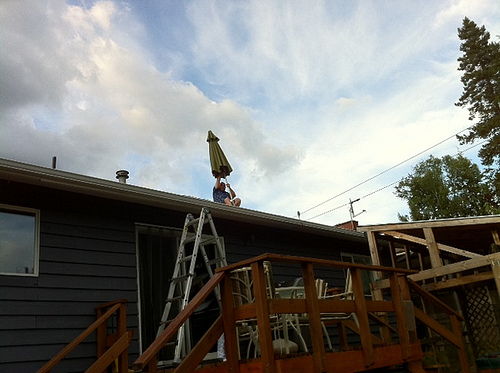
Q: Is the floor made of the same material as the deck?
A: Yes, both the floor and the deck are made of wood.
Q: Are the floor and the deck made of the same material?
A: Yes, both the floor and the deck are made of wood.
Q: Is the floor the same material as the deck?
A: Yes, both the floor and the deck are made of wood.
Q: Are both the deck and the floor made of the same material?
A: Yes, both the deck and the floor are made of wood.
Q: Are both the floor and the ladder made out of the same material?
A: No, the floor is made of wood and the ladder is made of metal.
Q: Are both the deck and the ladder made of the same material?
A: No, the deck is made of wood and the ladder is made of metal.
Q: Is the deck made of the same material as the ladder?
A: No, the deck is made of wood and the ladder is made of metal.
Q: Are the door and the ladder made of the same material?
A: No, the door is made of glass and the ladder is made of metal.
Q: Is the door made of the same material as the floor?
A: No, the door is made of glass and the floor is made of wood.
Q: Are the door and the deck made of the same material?
A: No, the door is made of glass and the deck is made of wood.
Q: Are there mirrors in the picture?
A: No, there are no mirrors.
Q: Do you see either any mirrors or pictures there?
A: No, there are no mirrors or pictures.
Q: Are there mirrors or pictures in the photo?
A: No, there are no mirrors or pictures.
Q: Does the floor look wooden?
A: Yes, the floor is wooden.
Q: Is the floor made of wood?
A: Yes, the floor is made of wood.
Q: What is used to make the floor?
A: The floor is made of wood.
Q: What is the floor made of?
A: The floor is made of wood.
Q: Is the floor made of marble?
A: No, the floor is made of wood.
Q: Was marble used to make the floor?
A: No, the floor is made of wood.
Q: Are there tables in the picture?
A: Yes, there is a table.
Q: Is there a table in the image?
A: Yes, there is a table.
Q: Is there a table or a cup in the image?
A: Yes, there is a table.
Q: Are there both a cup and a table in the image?
A: No, there is a table but no cups.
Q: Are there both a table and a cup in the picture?
A: No, there is a table but no cups.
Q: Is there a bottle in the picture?
A: No, there are no bottles.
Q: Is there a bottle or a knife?
A: No, there are no bottles or knives.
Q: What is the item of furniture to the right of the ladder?
A: The piece of furniture is a table.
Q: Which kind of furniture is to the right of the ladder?
A: The piece of furniture is a table.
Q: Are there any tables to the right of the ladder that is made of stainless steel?
A: Yes, there is a table to the right of the ladder.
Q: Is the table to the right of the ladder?
A: Yes, the table is to the right of the ladder.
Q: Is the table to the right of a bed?
A: No, the table is to the right of the ladder.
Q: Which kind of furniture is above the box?
A: The piece of furniture is a table.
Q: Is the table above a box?
A: Yes, the table is above a box.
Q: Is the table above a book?
A: No, the table is above a box.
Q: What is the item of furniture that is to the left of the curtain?
A: The piece of furniture is a table.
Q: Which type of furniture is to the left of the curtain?
A: The piece of furniture is a table.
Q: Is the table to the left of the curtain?
A: Yes, the table is to the left of the curtain.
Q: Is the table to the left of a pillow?
A: No, the table is to the left of the curtain.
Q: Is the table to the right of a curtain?
A: No, the table is to the left of a curtain.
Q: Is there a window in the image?
A: Yes, there is a window.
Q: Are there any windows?
A: Yes, there is a window.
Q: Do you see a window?
A: Yes, there is a window.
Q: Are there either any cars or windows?
A: Yes, there is a window.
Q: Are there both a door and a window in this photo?
A: Yes, there are both a window and a door.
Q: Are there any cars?
A: No, there are no cars.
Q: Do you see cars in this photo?
A: No, there are no cars.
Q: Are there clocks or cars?
A: No, there are no cars or clocks.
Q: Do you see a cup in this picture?
A: No, there are no cups.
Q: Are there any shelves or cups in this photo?
A: No, there are no cups or shelves.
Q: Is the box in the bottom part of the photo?
A: Yes, the box is in the bottom of the image.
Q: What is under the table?
A: The box is under the table.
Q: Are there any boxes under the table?
A: Yes, there is a box under the table.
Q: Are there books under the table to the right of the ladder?
A: No, there is a box under the table.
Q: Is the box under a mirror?
A: No, the box is under a table.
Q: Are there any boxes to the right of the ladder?
A: Yes, there is a box to the right of the ladder.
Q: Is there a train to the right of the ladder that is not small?
A: No, there is a box to the right of the ladder.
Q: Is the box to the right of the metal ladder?
A: Yes, the box is to the right of the ladder.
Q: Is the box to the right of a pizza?
A: No, the box is to the right of the ladder.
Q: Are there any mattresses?
A: No, there are no mattresses.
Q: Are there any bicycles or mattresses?
A: No, there are no mattresses or bicycles.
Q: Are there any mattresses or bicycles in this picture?
A: No, there are no mattresses or bicycles.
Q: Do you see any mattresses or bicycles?
A: No, there are no mattresses or bicycles.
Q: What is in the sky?
A: The clouds are in the sky.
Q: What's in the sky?
A: The clouds are in the sky.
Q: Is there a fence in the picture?
A: No, there are no fences.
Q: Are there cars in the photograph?
A: No, there are no cars.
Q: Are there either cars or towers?
A: No, there are no cars or towers.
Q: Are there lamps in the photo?
A: No, there are no lamps.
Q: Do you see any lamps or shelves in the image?
A: No, there are no lamps or shelves.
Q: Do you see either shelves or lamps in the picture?
A: No, there are no lamps or shelves.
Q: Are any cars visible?
A: No, there are no cars.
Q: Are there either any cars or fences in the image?
A: No, there are no cars or fences.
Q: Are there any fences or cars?
A: No, there are no cars or fences.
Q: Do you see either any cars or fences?
A: No, there are no cars or fences.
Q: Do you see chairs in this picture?
A: Yes, there is a chair.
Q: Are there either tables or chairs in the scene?
A: Yes, there is a chair.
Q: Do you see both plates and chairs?
A: No, there is a chair but no plates.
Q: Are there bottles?
A: No, there are no bottles.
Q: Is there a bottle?
A: No, there are no bottles.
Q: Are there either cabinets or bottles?
A: No, there are no bottles or cabinets.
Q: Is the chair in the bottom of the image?
A: Yes, the chair is in the bottom of the image.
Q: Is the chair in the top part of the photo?
A: No, the chair is in the bottom of the image.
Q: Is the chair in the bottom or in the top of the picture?
A: The chair is in the bottom of the image.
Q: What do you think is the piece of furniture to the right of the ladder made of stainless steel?
A: The piece of furniture is a chair.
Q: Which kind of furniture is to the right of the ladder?
A: The piece of furniture is a chair.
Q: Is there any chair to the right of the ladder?
A: Yes, there is a chair to the right of the ladder.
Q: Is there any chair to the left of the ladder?
A: No, the chair is to the right of the ladder.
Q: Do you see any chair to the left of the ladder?
A: No, the chair is to the right of the ladder.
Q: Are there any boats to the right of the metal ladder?
A: No, there is a chair to the right of the ladder.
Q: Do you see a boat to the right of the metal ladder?
A: No, there is a chair to the right of the ladder.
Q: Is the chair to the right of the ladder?
A: Yes, the chair is to the right of the ladder.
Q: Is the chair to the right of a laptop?
A: No, the chair is to the right of the ladder.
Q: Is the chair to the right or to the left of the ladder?
A: The chair is to the right of the ladder.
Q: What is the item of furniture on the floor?
A: The piece of furniture is a chair.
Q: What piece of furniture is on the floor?
A: The piece of furniture is a chair.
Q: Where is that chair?
A: The chair is on the floor.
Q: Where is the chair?
A: The chair is on the floor.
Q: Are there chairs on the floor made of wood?
A: Yes, there is a chair on the floor.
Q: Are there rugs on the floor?
A: No, there is a chair on the floor.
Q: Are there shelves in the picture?
A: No, there are no shelves.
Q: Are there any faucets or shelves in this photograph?
A: No, there are no shelves or faucets.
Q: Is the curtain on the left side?
A: No, the curtain is on the right of the image.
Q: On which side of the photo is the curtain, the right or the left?
A: The curtain is on the right of the image.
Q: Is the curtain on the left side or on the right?
A: The curtain is on the right of the image.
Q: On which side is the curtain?
A: The curtain is on the right of the image.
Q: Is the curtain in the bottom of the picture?
A: Yes, the curtain is in the bottom of the image.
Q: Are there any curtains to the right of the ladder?
A: Yes, there is a curtain to the right of the ladder.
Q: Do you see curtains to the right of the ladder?
A: Yes, there is a curtain to the right of the ladder.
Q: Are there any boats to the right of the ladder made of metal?
A: No, there is a curtain to the right of the ladder.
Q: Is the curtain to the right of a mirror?
A: No, the curtain is to the right of a ladder.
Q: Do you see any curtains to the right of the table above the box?
A: Yes, there is a curtain to the right of the table.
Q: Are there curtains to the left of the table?
A: No, the curtain is to the right of the table.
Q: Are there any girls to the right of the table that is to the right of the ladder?
A: No, there is a curtain to the right of the table.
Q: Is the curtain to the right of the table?
A: Yes, the curtain is to the right of the table.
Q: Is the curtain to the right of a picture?
A: No, the curtain is to the right of the table.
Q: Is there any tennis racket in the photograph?
A: No, there are no rackets.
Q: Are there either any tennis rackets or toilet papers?
A: No, there are no tennis rackets or toilet papers.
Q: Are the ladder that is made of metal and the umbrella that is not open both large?
A: Yes, both the ladder and the umbrella are large.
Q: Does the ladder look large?
A: Yes, the ladder is large.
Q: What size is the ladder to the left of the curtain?
A: The ladder is large.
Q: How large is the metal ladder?
A: The ladder is large.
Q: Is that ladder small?
A: No, the ladder is large.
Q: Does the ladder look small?
A: No, the ladder is large.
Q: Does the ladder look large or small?
A: The ladder is large.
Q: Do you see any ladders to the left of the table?
A: Yes, there is a ladder to the left of the table.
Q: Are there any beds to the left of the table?
A: No, there is a ladder to the left of the table.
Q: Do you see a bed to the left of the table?
A: No, there is a ladder to the left of the table.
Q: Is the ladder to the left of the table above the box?
A: Yes, the ladder is to the left of the table.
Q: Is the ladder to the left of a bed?
A: No, the ladder is to the left of the table.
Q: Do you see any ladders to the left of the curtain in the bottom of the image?
A: Yes, there is a ladder to the left of the curtain.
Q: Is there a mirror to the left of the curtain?
A: No, there is a ladder to the left of the curtain.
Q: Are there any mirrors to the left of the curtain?
A: No, there is a ladder to the left of the curtain.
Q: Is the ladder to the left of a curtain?
A: Yes, the ladder is to the left of a curtain.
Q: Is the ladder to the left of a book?
A: No, the ladder is to the left of a curtain.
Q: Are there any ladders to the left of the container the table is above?
A: Yes, there is a ladder to the left of the box.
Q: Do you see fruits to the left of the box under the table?
A: No, there is a ladder to the left of the box.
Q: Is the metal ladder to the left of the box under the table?
A: Yes, the ladder is to the left of the box.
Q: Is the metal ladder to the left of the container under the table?
A: Yes, the ladder is to the left of the box.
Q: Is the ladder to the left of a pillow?
A: No, the ladder is to the left of the box.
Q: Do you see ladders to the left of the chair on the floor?
A: Yes, there is a ladder to the left of the chair.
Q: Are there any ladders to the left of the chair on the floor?
A: Yes, there is a ladder to the left of the chair.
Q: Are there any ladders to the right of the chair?
A: No, the ladder is to the left of the chair.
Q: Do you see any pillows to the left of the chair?
A: No, there is a ladder to the left of the chair.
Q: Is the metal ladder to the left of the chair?
A: Yes, the ladder is to the left of the chair.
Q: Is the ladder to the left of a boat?
A: No, the ladder is to the left of the chair.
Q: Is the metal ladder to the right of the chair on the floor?
A: No, the ladder is to the left of the chair.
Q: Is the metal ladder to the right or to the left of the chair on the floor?
A: The ladder is to the left of the chair.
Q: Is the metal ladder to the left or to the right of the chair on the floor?
A: The ladder is to the left of the chair.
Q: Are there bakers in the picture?
A: No, there are no bakers.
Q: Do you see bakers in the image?
A: No, there are no bakers.